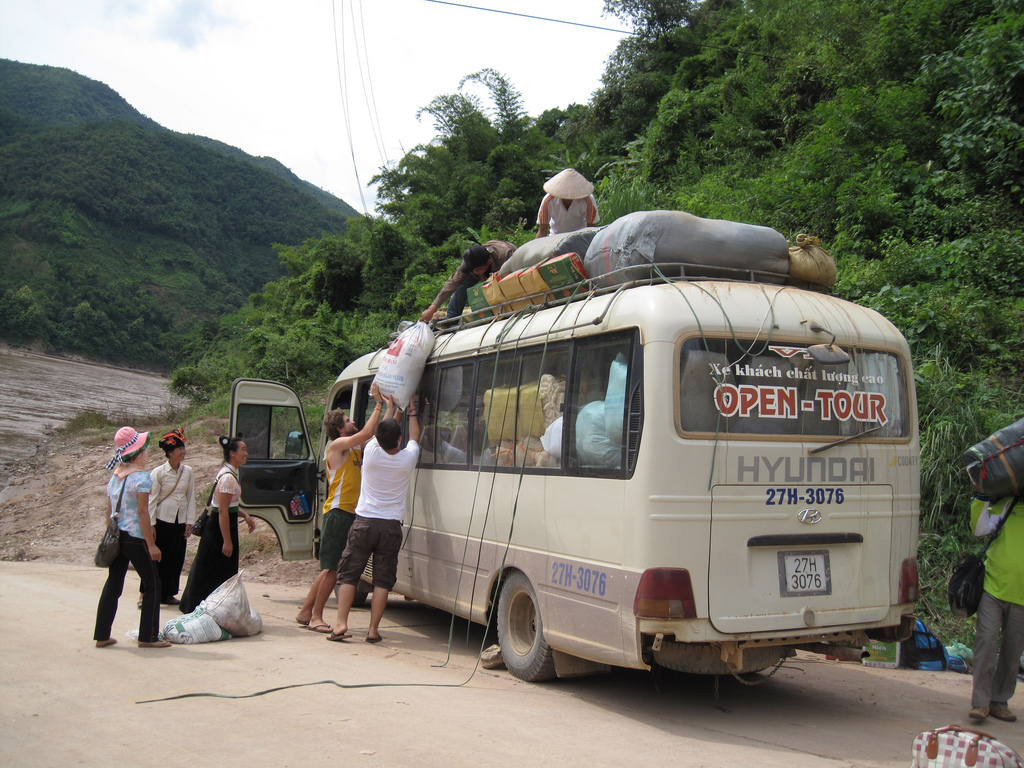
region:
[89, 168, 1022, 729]
the people near the beige bus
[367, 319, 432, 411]
the large white bag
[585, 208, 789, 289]
the large gray bag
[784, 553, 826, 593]
the license plate is white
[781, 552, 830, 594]
the black numbers and letters on the white license plate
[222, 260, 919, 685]
the door to the bus is open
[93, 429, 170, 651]
the woman is wearing a pink hat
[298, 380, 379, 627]
the man is wearing green shorts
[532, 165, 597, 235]
the person is wearing a hat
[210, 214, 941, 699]
an old white bus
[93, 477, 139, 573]
a woman's black purse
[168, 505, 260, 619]
a woman's long black skirt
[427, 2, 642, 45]
a long electrical power line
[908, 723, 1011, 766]
a brown and white bag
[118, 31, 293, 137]
a white cloud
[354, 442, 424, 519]
a man's white short sleeve shirt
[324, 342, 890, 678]
a large white bus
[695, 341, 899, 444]
writing on the window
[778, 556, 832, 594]
the license plate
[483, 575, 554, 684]
the tire on the bus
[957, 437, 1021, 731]
a person in a green shirt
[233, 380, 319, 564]
the door on the bus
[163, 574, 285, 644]
bags on the ground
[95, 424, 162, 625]
a person in a pink hat